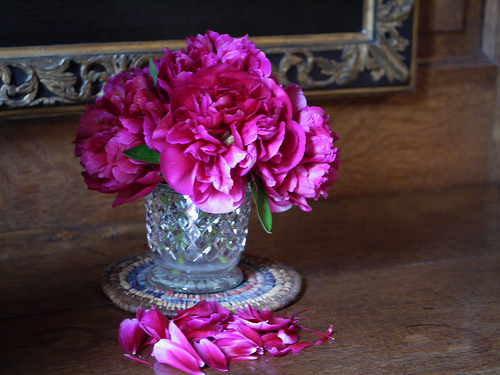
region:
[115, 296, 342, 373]
pink flower petals on table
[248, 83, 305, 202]
pink flower in vase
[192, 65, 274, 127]
pink flower in vase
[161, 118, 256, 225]
pink flower in vase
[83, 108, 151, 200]
pink flower in vase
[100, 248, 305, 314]
patterned circular coaster on table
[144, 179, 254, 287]
glass transparent flower vase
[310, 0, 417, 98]
patterned design on frame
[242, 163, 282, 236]
green leaf from flower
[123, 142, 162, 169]
green leaf from flower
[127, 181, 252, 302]
a small vase with flowers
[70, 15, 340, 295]
a vase with flowers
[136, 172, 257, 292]
a vase of glass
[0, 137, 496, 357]
a vase over a table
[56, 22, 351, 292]
purple flowers in a vase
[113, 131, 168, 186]
green leaves in middle of flowers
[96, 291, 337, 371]
flower petals on the table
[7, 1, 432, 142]
frame of a picture behind the vase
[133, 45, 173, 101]
green leave in middle of flowers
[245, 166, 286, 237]
green leave in middle of flowers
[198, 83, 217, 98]
this is a petal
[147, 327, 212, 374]
this is a fallen petal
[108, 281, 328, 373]
these are fallen petals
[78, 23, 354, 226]
these are the flowers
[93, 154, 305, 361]
this is a vase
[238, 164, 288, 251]
this is a leaf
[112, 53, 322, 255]
these are the leaves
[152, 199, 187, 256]
this is the glass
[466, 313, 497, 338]
this is the color brown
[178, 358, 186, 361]
this is the color pink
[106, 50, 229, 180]
Flowers in a vase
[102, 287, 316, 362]
Flower petals on the table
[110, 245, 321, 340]
Mat on a table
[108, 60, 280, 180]
flowers in the vase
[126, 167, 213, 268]
Crystal vase with flowers in it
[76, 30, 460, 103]
Picture behind flowers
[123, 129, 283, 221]
Green leafs in the flowers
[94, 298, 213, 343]
Flowers pedals on the table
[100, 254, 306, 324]
mat on the table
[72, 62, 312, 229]
flowers in a crystal vase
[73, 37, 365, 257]
Pink flowers are in a vase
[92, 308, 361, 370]
flower petals are on the floor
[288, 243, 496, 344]
the floor is made of wood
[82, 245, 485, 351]
A vase is on a multicolored coaster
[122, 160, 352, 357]
The vase is made of glass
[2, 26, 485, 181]
The vase is by a fireplace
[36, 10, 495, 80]
The fireplace is framed in black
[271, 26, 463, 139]
The fireplace has wood on the bottom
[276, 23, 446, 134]
Accents are on the fireplace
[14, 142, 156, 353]
The floorboards are made of wood